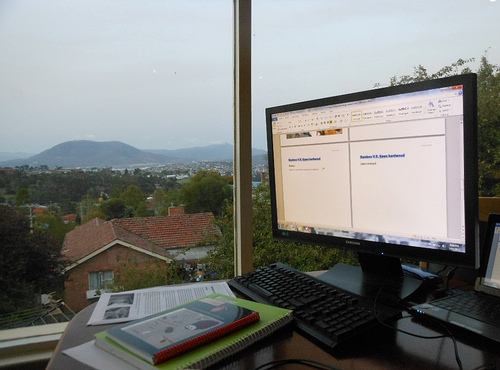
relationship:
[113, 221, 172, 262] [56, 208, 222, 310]
roof on house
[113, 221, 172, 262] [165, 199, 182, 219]
roof has chimney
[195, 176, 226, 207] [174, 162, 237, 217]
tree in distance